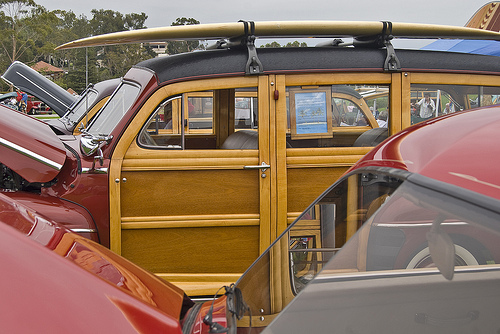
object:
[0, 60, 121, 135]
car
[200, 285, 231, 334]
windshield wiper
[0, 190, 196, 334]
hood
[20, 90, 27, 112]
people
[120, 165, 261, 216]
wood side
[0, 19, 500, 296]
car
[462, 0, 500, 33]
carving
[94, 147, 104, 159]
mirror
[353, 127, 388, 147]
backrest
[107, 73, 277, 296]
wooden doors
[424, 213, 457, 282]
mirror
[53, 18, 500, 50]
surfboard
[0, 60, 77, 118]
hood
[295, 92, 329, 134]
sign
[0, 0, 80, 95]
tree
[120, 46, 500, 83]
top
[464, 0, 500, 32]
fin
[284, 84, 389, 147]
window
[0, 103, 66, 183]
hood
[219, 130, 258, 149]
backrest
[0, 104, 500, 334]
car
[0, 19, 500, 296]
exterior